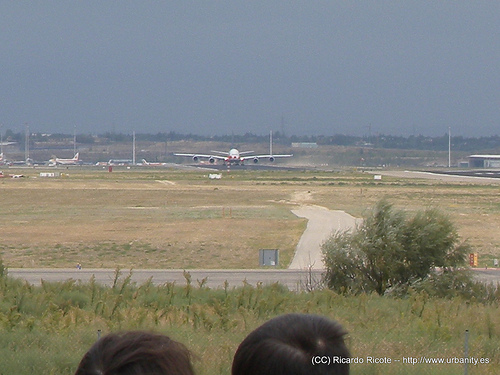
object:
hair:
[232, 313, 356, 375]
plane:
[174, 142, 286, 166]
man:
[76, 329, 191, 375]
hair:
[75, 329, 196, 375]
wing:
[173, 143, 225, 167]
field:
[0, 173, 499, 268]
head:
[72, 331, 201, 375]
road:
[284, 187, 364, 271]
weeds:
[1, 266, 500, 375]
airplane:
[44, 151, 84, 166]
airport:
[0, 150, 484, 172]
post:
[446, 122, 454, 170]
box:
[255, 245, 281, 267]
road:
[4, 263, 500, 293]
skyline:
[0, 0, 500, 151]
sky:
[1, 0, 483, 134]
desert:
[0, 171, 499, 267]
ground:
[0, 172, 290, 263]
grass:
[0, 177, 308, 268]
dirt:
[194, 162, 288, 172]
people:
[227, 311, 357, 375]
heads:
[232, 309, 353, 375]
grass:
[0, 256, 500, 375]